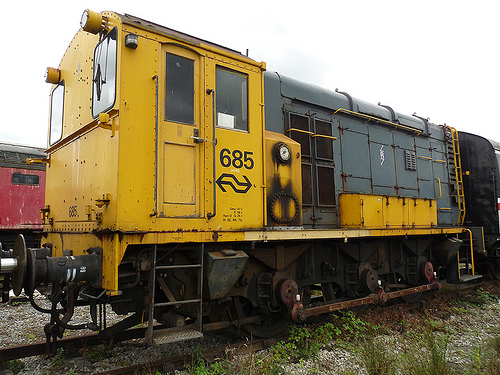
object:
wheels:
[230, 286, 312, 338]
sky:
[2, 3, 499, 163]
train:
[0, 8, 500, 349]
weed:
[275, 314, 330, 363]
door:
[161, 43, 202, 218]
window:
[167, 53, 194, 125]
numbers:
[220, 148, 254, 169]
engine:
[454, 129, 500, 251]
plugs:
[0, 233, 103, 296]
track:
[3, 273, 494, 369]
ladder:
[446, 126, 466, 224]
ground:
[15, 280, 499, 372]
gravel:
[288, 306, 499, 370]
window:
[216, 64, 250, 131]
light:
[80, 9, 105, 34]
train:
[1, 142, 51, 242]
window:
[92, 29, 116, 116]